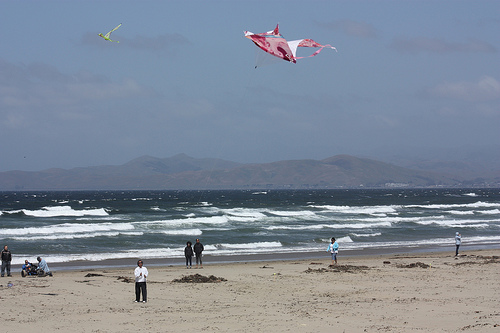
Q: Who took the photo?
A: Friend.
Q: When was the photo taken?
A: Afternoon.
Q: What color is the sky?
A: Blue.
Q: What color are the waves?
A: White.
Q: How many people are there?
A: Eight.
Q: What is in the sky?
A: Kite.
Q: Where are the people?
A: Beach.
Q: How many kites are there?
A: Two.